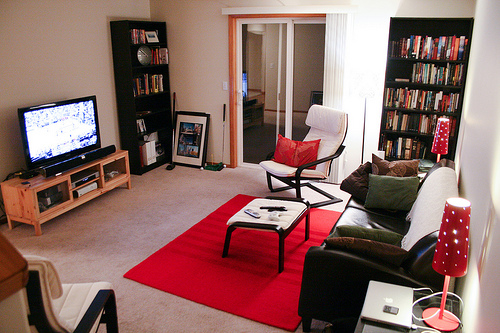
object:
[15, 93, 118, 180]
tv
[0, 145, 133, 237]
stand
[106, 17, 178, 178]
bookshelf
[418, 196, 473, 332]
lamp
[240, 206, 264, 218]
remote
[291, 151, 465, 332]
couch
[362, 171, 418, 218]
pillow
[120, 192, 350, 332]
rug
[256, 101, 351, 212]
chair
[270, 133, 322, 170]
pillow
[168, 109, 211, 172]
picture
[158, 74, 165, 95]
books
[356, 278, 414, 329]
laptop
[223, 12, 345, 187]
doorframe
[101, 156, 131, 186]
opening